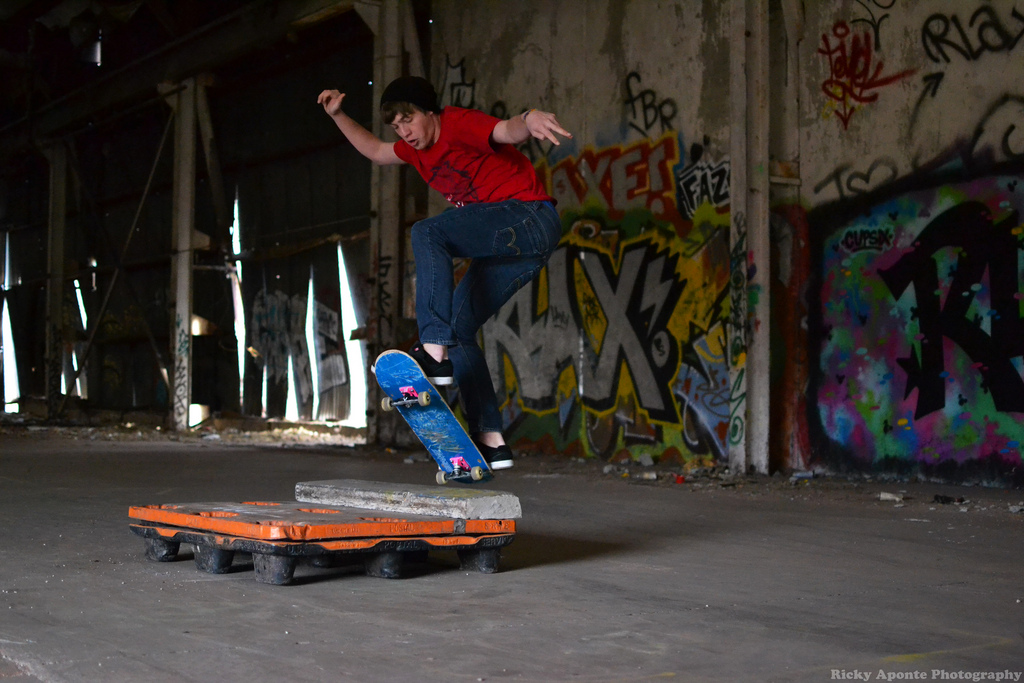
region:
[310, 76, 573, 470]
Man in a red shirt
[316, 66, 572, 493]
man on a skateboard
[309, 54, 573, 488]
man on a blue skateboard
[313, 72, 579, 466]
man wearing blue jeans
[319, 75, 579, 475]
man wearing a black hat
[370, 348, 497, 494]
the skateboard is the color blue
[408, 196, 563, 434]
The color of the jeans is blue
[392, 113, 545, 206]
The color of the shirt is red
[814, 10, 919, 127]
red graffiti on wall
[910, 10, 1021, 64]
black graffiti on wall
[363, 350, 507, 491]
blue skateboard on ground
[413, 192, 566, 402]
blue jeans on the boy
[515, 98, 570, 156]
the person's left hand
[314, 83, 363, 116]
the person's right hand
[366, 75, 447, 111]
hat on the person's head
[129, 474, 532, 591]
orange and black pallet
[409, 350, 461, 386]
black shoe on left foot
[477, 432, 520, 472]
black shoe on right foot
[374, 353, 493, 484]
A blue and pink skateboard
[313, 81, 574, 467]
A man with red shirt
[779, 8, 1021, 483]
Grafetti on stone wall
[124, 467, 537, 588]
Orange platform on the floor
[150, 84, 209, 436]
Pole lending on a wall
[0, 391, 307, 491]
Concrete floor in building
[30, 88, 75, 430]
Pole by the door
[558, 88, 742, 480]
Paint on the wall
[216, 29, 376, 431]
Door on the side of building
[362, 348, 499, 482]
a used blue skateboard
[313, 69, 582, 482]
a guy on a skateboard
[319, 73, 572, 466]
a guy wearing blue jeans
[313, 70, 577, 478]
a guy wearing a black hat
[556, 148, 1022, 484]
graffiti on a wall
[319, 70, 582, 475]
a guy wearing black sneakers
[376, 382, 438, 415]
front wheels of a skateboard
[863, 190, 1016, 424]
graffiti on a wall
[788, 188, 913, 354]
graffiti on a wall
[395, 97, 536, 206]
A young boy wearing a red shirt.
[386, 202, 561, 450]
A pair of blue jeans.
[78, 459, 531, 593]
A orange and white platform.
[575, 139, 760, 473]
Colorful graphiti on the wall behind the man.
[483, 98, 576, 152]
The young mans arm is in the air.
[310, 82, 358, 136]
The young man's hand is in the air.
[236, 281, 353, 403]
Graphit is on the door of the building.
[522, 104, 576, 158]
Hand of a man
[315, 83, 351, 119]
Hand of a man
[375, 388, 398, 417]
Wheel on a skateboard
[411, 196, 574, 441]
Jeans on a man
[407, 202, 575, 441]
Blue jeans on a man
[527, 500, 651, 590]
Shadow across the ground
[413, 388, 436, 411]
Wheel of a skateboard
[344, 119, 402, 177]
Arm of a man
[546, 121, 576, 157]
Fingers on a hand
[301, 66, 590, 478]
the boy is riding a skateboard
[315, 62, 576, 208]
the boy is wearing a red shirt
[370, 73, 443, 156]
the boy has brown hair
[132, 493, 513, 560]
an orange pallet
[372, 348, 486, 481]
a blue skateboard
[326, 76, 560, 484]
a man on a skateboard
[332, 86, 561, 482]
a skateboarder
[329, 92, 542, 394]
a man in a red shirt